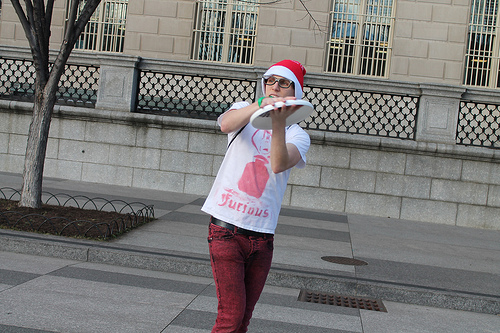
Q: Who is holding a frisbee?
A: Man in Santa hat.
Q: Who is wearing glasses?
A: Man in Santa hat.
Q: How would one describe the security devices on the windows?
A: Bars.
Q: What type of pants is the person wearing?
A: Red skinny jeans.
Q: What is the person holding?
A: White frisbee.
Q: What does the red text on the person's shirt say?
A: Furious.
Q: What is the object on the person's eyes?
A: Pair of glasses.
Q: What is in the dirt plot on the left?
A: Tree.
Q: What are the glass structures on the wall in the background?
A: Windows.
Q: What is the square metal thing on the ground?
A: Grate.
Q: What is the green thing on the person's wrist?
A: Bracelet.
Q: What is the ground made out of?
A: Stone.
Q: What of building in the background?
A: Windows.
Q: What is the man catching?
A: Frisbee.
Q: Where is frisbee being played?
A: Street.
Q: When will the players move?
A: Car comes.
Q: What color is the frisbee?
A: White.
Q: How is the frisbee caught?
A: Hands.